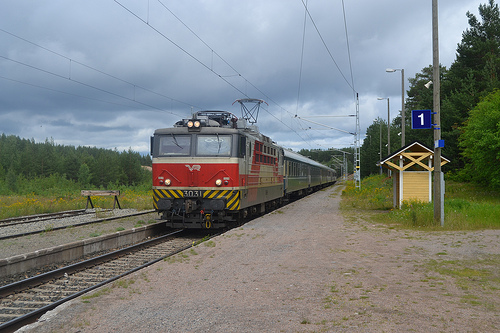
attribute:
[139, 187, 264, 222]
yellow stripes — black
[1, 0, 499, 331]
scene — outdoor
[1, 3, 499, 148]
sky — cloudy, stormy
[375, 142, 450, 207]
building — yellow, small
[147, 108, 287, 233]
engine — red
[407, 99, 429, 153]
sign — square, hanging, blue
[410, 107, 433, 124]
sign — small, square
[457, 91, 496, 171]
plants — green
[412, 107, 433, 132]
number 1 — written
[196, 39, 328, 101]
clouds — grey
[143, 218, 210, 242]
shadow — cast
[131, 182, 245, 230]
panel — striped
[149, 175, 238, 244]
engine — red 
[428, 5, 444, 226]
wooden pole — tall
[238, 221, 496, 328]
ground — bare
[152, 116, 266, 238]
train — red